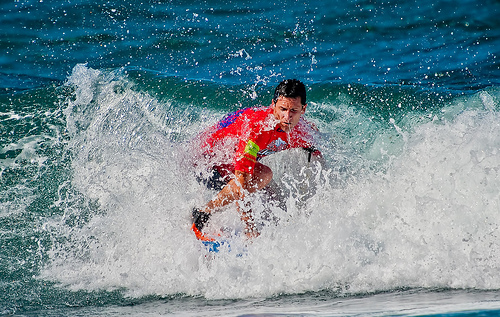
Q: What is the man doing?
A: Surfing.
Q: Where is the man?
A: In the water.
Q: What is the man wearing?
A: Wetsuit.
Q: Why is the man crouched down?
A: Balance.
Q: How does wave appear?
A: Foamy.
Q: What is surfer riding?
A: Board.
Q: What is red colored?
A: Wetsuit.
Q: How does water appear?
A: Rough and wavy.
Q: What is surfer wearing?
A: Red shirt.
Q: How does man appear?
A: Crouching down.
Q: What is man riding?
A: Small wave.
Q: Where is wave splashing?
A: Against water.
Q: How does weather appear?
A: Sunny.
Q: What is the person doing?
A: Surfing.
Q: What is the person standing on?
A: Surfboard.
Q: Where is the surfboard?
A: Water.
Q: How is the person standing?
A: Crouched.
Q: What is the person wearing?
A: Red short sleeve shirt.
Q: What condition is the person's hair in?
A: Wet.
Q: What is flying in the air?
A: Water splash.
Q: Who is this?
A: Surfer.